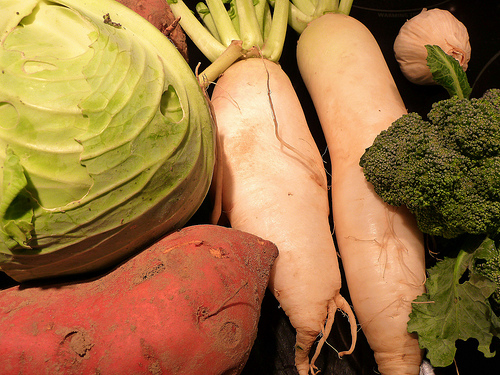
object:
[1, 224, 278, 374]
sweet potato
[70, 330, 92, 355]
dirt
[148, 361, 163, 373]
dirt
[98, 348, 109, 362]
dirt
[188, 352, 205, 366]
dirt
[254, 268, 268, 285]
dirt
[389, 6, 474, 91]
garlic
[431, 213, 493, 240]
water skiing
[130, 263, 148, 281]
dirt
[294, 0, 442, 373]
carrots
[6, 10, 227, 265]
cabbage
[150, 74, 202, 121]
hole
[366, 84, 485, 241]
broccoli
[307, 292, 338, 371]
root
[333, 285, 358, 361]
root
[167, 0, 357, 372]
carrot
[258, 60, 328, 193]
split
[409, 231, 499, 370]
spinach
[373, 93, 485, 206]
head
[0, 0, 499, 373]
table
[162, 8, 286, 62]
stems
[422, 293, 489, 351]
leaf